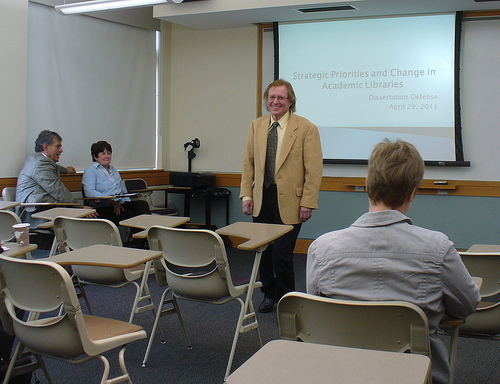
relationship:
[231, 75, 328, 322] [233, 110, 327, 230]
man wearing coat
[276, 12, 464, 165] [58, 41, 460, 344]
screen in room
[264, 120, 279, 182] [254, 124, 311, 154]
man's tie on shirt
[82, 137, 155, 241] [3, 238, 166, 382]
person sitting at desk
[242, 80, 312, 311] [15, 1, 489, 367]
person standing in front of class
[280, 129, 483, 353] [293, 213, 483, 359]
person on desk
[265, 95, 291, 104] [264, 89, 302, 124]
eyeglasses on face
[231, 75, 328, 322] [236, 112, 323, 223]
man in jacket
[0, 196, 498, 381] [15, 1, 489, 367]
desks in a class